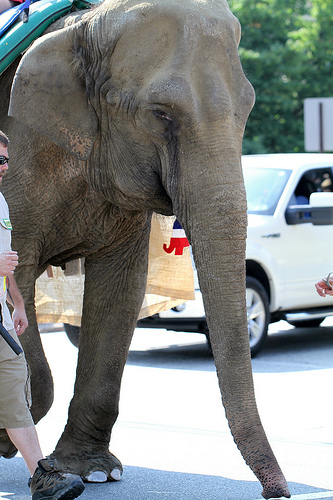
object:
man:
[0, 129, 86, 498]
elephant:
[0, 0, 289, 499]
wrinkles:
[0, 132, 150, 264]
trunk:
[156, 127, 292, 497]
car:
[158, 152, 332, 358]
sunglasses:
[0, 153, 9, 166]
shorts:
[0, 313, 34, 430]